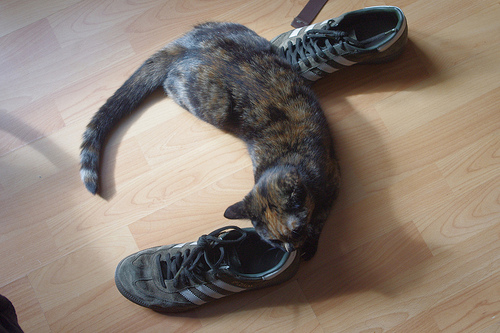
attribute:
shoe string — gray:
[220, 225, 252, 243]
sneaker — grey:
[116, 222, 291, 314]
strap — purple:
[283, 0, 360, 25]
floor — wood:
[9, 30, 490, 330]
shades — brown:
[121, 130, 201, 235]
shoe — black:
[270, 5, 407, 80]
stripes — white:
[179, 280, 245, 304]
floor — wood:
[1, 1, 497, 330]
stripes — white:
[180, 273, 233, 333]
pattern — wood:
[1, 243, 90, 316]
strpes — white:
[174, 270, 232, 333]